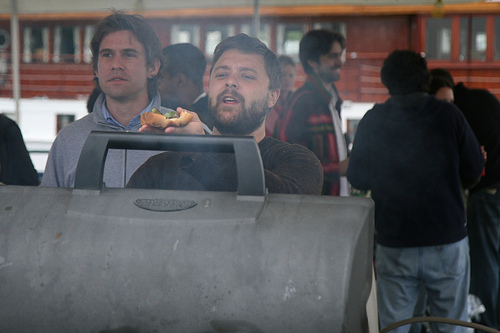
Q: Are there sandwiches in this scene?
A: Yes, there is a sandwich.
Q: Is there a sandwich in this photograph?
A: Yes, there is a sandwich.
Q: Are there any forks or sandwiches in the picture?
A: Yes, there is a sandwich.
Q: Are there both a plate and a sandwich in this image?
A: No, there is a sandwich but no plates.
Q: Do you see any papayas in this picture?
A: No, there are no papayas.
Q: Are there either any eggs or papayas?
A: No, there are no papayas or eggs.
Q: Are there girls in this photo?
A: No, there are no girls.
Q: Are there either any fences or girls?
A: No, there are no girls or fences.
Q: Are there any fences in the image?
A: No, there are no fences.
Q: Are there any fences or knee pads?
A: No, there are no fences or knee pads.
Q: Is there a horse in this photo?
A: No, there are no horses.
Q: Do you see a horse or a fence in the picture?
A: No, there are no horses or fences.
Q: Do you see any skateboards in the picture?
A: No, there are no skateboards.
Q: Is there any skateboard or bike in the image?
A: No, there are no skateboards or bikes.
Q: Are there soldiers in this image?
A: No, there are no soldiers.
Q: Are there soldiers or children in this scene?
A: No, there are no soldiers or children.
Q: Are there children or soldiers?
A: No, there are no soldiers or children.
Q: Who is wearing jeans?
A: The man is wearing jeans.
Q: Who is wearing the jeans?
A: The man is wearing jeans.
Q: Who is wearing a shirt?
A: The man is wearing a shirt.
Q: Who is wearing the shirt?
A: The man is wearing a shirt.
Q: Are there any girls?
A: No, there are no girls.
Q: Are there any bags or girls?
A: No, there are no girls or bags.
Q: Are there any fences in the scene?
A: No, there are no fences.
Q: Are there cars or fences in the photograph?
A: No, there are no fences or cars.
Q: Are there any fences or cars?
A: No, there are no fences or cars.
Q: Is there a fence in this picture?
A: No, there are no fences.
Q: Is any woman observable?
A: No, there are no women.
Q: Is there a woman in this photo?
A: No, there are no women.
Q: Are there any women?
A: No, there are no women.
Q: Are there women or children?
A: No, there are no women or children.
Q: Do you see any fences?
A: No, there are no fences.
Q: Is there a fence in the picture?
A: No, there are no fences.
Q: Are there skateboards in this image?
A: No, there are no skateboards.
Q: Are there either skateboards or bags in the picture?
A: No, there are no skateboards or bags.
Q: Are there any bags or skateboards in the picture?
A: No, there are no skateboards or bags.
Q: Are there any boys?
A: No, there are no boys.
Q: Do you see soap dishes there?
A: No, there are no soap dishes.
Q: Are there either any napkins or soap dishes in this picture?
A: No, there are no soap dishes or napkins.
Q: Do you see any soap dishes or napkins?
A: No, there are no soap dishes or napkins.